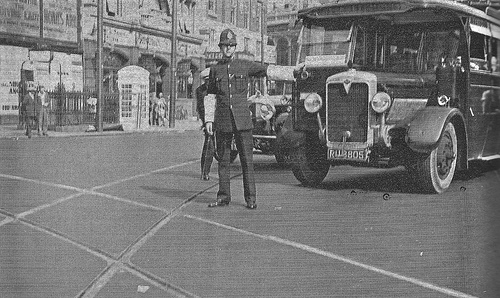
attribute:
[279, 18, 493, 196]
truck — old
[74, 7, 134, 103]
pole — tall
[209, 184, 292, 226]
shoes — black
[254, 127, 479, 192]
wheels — black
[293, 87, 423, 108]
lights — round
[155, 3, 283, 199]
man — standing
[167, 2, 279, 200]
man — standing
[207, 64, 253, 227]
man — standing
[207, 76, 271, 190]
man — standing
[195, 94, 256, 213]
man — standing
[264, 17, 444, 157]
bus — driving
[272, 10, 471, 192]
bus — large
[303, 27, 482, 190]
bus — large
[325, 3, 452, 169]
bus — large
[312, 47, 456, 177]
bus — large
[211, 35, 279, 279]
officer — directing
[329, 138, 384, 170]
plate — grey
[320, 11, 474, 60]
windows — clear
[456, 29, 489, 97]
windows — open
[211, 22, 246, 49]
helmet — black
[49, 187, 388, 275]
street — black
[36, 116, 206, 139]
sidewalk — tan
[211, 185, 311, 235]
shoes — black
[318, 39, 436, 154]
bus — stopped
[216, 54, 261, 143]
uniform — black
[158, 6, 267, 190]
policeman — standing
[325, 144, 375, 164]
plate — license 